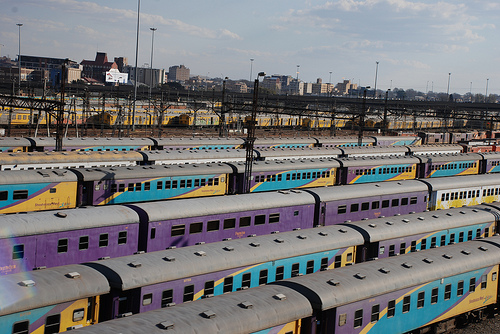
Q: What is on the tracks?
A: Trains.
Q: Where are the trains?
A: Next to each other.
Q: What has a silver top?
A: Trains.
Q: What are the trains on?
A: Tracks.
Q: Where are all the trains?
A: Train yard.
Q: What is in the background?
A: Buildings.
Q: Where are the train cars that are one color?
A: Third row.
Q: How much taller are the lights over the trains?
A: About 3 times taller.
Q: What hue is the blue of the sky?
A: Light.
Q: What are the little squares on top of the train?
A: Vents.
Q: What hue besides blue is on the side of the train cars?
A: Yellow.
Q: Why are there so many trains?
A: Train depot.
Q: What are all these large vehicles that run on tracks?
A: Trains.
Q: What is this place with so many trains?
A: Train depot.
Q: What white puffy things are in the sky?
A: Clouds.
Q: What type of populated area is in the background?
A: City.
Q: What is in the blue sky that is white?
A: Clouds.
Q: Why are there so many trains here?
A: Train station.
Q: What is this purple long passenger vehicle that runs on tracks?
A: Train.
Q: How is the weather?
A: Sunny.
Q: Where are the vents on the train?
A: Roof.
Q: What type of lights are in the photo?
A: Street.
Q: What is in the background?
A: Buildings.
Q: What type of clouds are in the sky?
A: Cumulus.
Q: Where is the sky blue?
A: Between clouds.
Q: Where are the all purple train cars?
A: Third row.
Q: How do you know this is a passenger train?
A: Windows.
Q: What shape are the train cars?
A: Rectangular.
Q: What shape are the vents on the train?
A: Square.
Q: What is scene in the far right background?
A: Sky.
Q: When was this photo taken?
A: Daytime.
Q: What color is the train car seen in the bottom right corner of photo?
A: Blue, purple & yellow.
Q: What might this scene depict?
A: Train yard.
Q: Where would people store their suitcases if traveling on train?
A: Baggage car.